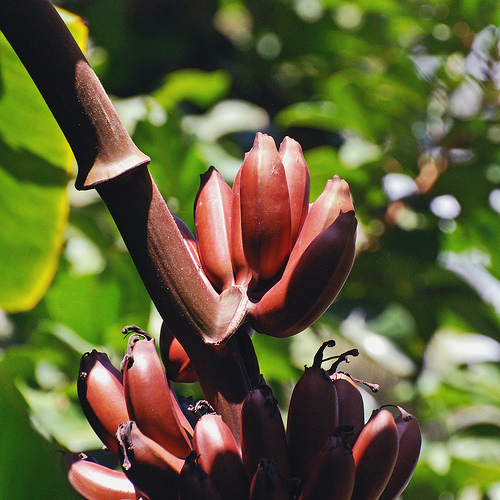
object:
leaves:
[151, 66, 232, 111]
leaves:
[412, 325, 498, 435]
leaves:
[181, 98, 271, 144]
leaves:
[211, 0, 253, 51]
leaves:
[13, 375, 106, 454]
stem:
[120, 324, 152, 342]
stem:
[375, 403, 413, 421]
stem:
[335, 369, 381, 394]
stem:
[187, 399, 217, 415]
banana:
[158, 319, 201, 385]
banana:
[74, 348, 132, 459]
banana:
[193, 164, 232, 284]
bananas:
[191, 411, 244, 499]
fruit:
[177, 394, 202, 428]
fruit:
[173, 461, 216, 500]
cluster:
[157, 131, 357, 385]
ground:
[0, 0, 499, 499]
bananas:
[238, 387, 286, 474]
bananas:
[114, 418, 185, 500]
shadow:
[254, 214, 357, 339]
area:
[0, 0, 499, 499]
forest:
[0, 3, 498, 498]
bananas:
[392, 414, 421, 499]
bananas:
[349, 410, 398, 499]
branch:
[0, 0, 284, 461]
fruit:
[247, 460, 282, 499]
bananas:
[331, 371, 364, 449]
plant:
[420, 340, 499, 499]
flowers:
[311, 338, 336, 366]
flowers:
[330, 346, 360, 369]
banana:
[250, 207, 358, 338]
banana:
[227, 146, 248, 268]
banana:
[280, 174, 356, 282]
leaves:
[273, 97, 364, 143]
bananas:
[285, 364, 340, 443]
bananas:
[300, 443, 355, 499]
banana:
[277, 134, 310, 247]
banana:
[120, 336, 199, 464]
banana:
[237, 130, 291, 281]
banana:
[168, 211, 206, 279]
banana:
[58, 451, 143, 499]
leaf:
[0, 0, 89, 314]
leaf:
[135, 66, 225, 232]